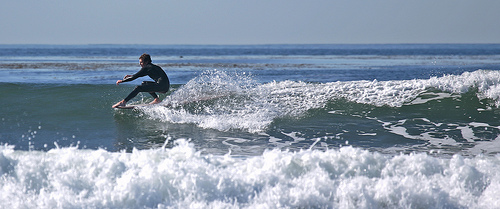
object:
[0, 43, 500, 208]
saltwater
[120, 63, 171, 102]
wetsuit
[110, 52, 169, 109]
surfer